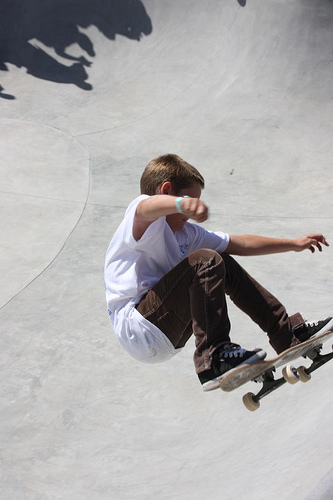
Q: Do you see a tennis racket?
A: No, there are no rackets.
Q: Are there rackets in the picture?
A: No, there are no rackets.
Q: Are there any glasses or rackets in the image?
A: No, there are no rackets or glasses.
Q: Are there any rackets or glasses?
A: No, there are no rackets or glasses.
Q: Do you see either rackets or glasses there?
A: No, there are no rackets or glasses.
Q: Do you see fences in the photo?
A: No, there are no fences.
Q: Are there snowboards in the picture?
A: No, there are no snowboards.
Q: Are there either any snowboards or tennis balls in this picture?
A: No, there are no snowboards or tennis balls.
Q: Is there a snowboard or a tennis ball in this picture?
A: No, there are no snowboards or tennis balls.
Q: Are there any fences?
A: No, there are no fences.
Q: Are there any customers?
A: No, there are no customers.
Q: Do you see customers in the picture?
A: No, there are no customers.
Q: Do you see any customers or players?
A: No, there are no customers or players.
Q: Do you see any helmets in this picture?
A: No, there are no helmets.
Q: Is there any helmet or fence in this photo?
A: No, there are no helmets or fences.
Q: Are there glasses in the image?
A: No, there are no glasses.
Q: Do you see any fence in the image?
A: No, there are no fences.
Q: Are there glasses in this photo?
A: No, there are no glasses.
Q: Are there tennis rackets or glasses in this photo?
A: No, there are no glasses or tennis rackets.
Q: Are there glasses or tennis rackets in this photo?
A: No, there are no glasses or tennis rackets.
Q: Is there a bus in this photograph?
A: No, there are no buses.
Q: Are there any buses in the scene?
A: No, there are no buses.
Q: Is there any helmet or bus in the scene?
A: No, there are no buses or helmets.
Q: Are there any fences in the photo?
A: No, there are no fences.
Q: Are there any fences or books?
A: No, there are no fences or books.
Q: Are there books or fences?
A: No, there are no fences or books.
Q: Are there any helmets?
A: No, there are no helmets.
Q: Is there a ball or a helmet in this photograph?
A: No, there are no helmets or balls.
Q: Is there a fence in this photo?
A: No, there are no fences.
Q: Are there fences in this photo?
A: No, there are no fences.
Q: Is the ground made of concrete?
A: Yes, the ground is made of concrete.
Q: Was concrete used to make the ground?
A: Yes, the ground is made of concrete.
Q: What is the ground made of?
A: The ground is made of concrete.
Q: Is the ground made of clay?
A: No, the ground is made of cement.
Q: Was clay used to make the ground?
A: No, the ground is made of cement.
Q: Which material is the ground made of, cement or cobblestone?
A: The ground is made of cement.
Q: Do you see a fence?
A: No, there are no fences.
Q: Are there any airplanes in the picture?
A: No, there are no airplanes.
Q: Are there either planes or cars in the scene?
A: No, there are no planes or cars.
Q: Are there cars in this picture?
A: No, there are no cars.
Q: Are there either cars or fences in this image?
A: No, there are no cars or fences.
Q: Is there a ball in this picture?
A: No, there are no balls.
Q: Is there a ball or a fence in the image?
A: No, there are no balls or fences.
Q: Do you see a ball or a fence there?
A: No, there are no balls or fences.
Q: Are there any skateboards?
A: Yes, there is a skateboard.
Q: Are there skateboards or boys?
A: Yes, there is a skateboard.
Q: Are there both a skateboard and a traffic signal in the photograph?
A: No, there is a skateboard but no traffic lights.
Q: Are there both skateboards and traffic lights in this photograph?
A: No, there is a skateboard but no traffic lights.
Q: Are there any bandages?
A: No, there are no bandages.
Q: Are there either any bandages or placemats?
A: No, there are no bandages or placemats.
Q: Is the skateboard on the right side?
A: Yes, the skateboard is on the right of the image.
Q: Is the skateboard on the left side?
A: No, the skateboard is on the right of the image.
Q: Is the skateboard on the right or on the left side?
A: The skateboard is on the right of the image.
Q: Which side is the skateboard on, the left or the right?
A: The skateboard is on the right of the image.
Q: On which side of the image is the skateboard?
A: The skateboard is on the right of the image.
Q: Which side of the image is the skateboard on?
A: The skateboard is on the right of the image.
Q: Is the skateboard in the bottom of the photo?
A: Yes, the skateboard is in the bottom of the image.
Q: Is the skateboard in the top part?
A: No, the skateboard is in the bottom of the image.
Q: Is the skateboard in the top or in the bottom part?
A: The skateboard is in the bottom of the image.